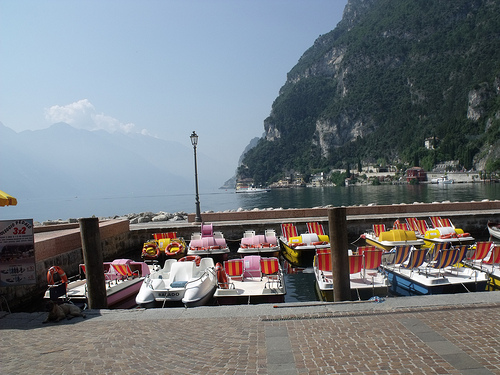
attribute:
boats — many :
[63, 201, 293, 302]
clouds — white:
[41, 97, 181, 144]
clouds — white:
[44, 98, 172, 143]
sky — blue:
[3, 4, 495, 218]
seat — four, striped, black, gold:
[385, 243, 412, 264]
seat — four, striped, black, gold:
[401, 245, 428, 274]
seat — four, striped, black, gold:
[432, 247, 457, 272]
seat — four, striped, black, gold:
[451, 243, 467, 265]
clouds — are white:
[61, 70, 116, 113]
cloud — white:
[44, 98, 160, 138]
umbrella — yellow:
[1, 192, 23, 197]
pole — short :
[77, 217, 109, 309]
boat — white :
[35, 248, 145, 327]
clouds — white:
[42, 98, 143, 133]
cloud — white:
[0, 125, 177, 195]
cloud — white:
[38, 101, 166, 140]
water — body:
[8, 185, 484, 207]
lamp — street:
[186, 130, 198, 151]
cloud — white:
[41, 94, 185, 146]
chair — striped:
[217, 255, 252, 287]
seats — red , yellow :
[217, 256, 284, 283]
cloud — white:
[8, 93, 160, 145]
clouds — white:
[44, 99, 149, 135]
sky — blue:
[1, 1, 349, 168]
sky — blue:
[2, 3, 349, 191]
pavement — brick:
[1, 299, 499, 372]